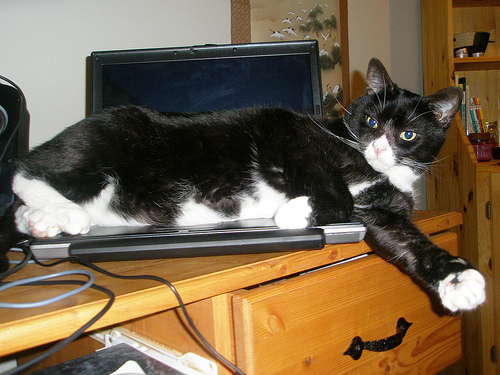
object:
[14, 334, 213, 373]
keyboard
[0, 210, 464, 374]
desk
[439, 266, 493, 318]
paw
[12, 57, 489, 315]
cat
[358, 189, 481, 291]
arm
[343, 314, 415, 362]
handle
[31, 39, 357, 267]
laptop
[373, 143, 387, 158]
nose tip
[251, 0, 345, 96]
birds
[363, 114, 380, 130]
cat eye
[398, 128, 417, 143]
cat eye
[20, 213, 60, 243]
cat paws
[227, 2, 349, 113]
decoration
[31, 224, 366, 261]
keyboard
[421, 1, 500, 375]
cabinet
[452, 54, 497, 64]
shelf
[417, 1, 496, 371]
shelf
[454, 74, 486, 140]
books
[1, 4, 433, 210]
wall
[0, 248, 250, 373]
cord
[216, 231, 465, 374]
drawer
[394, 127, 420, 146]
pupil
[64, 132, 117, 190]
fur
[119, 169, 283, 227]
stomach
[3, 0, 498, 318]
view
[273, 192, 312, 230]
paw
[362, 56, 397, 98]
ear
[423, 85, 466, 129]
ear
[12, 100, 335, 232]
torso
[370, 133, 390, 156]
nose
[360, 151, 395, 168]
mouth